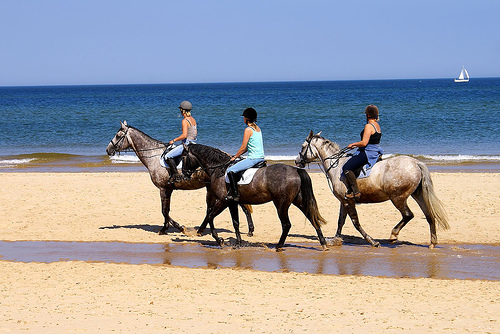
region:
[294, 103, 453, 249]
white horse on beach with woman wthout bank rupt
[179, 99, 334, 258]
woman wearing blue striped tank top on brown horse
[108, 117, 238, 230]
grey horse woth woman in gray tank top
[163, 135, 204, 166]
woman has blond hair and is wearing jeans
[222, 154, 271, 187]
woman has dark hair and is wearing jeans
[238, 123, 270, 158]
womanhas dark hair and is wearing jeans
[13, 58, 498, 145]
bright blue ocean water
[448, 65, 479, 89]
white sail boat in water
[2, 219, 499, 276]
wet ptch in sand from ocean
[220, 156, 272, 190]
black saddle with white padding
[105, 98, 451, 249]
three people riding horses on the beach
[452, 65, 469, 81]
a white sailboat on the sea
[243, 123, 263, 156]
woman wearing baby blue tank top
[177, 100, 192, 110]
woman wearing a gray helmet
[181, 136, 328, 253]
a brown horse walking on the beach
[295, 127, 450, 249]
a white horse on the beach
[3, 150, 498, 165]
gentle waves washing on the shore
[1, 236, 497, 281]
a path of wet sand on the beach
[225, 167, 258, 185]
a white saddle on a horse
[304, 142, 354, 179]
a woman holding a horse's reigns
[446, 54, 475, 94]
A white sailing boat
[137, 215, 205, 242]
Horses feet on the white sand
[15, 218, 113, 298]
Water in the middle of the sand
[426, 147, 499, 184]
Waves rushing on the coast line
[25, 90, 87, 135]
Blue and green sea at the background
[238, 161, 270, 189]
White sadle at the back of the horse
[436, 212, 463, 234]
Tip of the horse tail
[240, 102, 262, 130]
A lady wearing black cap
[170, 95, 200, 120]
Lady with a blonde hair is wearing a gray cap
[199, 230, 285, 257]
Horses feet trumpling on the mud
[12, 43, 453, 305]
this is along a coast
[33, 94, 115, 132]
the ocean is blue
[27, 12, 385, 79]
the horizon is very light blue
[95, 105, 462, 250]
the people are on horseback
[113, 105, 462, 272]
there are three horses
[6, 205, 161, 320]
the ground here is very sandy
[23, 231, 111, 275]
the sand here is wet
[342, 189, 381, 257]
this is a horse`s leg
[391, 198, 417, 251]
this is a horse`s leg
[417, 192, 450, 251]
this is a horse`s leg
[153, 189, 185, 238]
this is a horse`s leg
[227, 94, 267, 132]
this is a peson`s head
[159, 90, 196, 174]
this is a person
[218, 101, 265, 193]
this is a person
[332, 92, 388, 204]
this is a person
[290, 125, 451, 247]
this is a horse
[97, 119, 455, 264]
these are horses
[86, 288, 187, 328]
Large body of sand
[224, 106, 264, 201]
person sitting on top of horse